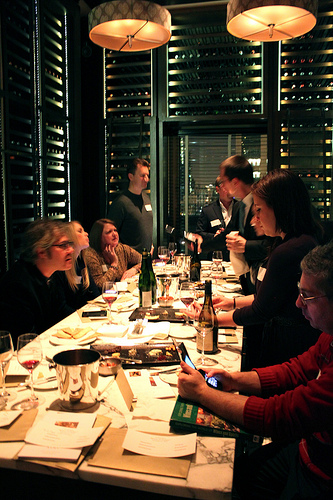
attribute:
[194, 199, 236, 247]
blazer — black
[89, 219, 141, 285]
lady — older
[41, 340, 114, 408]
container — metal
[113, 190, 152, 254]
sweater — gray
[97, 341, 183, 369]
plate — half empty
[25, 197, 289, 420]
table — cluttered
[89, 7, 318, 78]
lights — gray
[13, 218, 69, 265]
hair — gray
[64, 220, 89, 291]
hair — blond